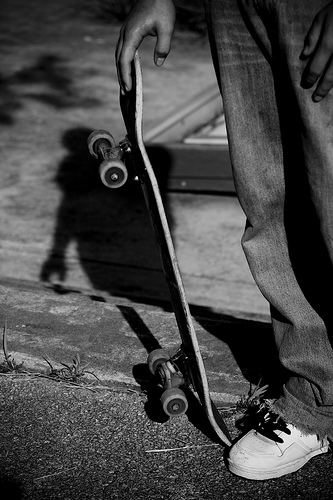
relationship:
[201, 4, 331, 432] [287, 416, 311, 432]
jeans with no hem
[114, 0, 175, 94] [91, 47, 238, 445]
hand holding skateboard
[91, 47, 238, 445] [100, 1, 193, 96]
skateboard with hand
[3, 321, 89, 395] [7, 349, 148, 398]
grass growing in cracks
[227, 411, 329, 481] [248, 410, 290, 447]
shoe with lace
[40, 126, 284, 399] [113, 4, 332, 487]
shadow of a boy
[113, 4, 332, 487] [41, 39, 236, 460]
boy and h skateboard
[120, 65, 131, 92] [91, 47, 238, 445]
fingertips holding up a skateboard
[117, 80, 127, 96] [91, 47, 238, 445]
fingertips holding up a skateboard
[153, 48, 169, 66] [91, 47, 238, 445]
fingertips holding up a skateboard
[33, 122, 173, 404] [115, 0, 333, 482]
shadow of standing boy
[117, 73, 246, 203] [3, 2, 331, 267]
railing on ground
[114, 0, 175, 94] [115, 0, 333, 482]
hand of a boy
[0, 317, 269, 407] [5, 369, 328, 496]
grass growing next to cement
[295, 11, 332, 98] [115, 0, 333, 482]
hand resting by side of boy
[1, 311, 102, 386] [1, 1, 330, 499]
plants growing in ground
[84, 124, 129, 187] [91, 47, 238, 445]
wheels on skateboard